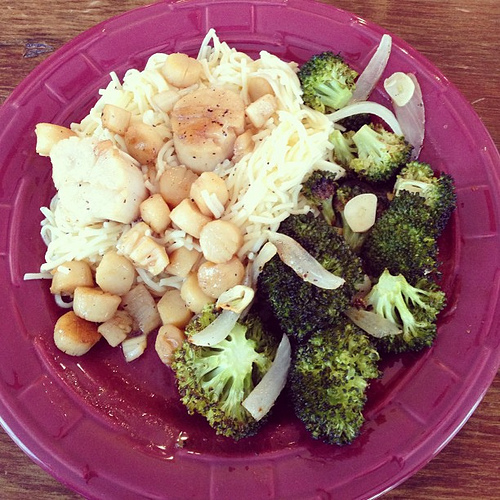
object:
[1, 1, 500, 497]
table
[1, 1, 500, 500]
plate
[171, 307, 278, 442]
broccoli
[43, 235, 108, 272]
noodle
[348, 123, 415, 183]
broccoli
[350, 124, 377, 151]
stem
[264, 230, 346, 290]
onion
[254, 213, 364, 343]
broccoli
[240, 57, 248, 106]
noodle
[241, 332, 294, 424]
onion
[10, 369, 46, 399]
groove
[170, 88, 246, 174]
meat